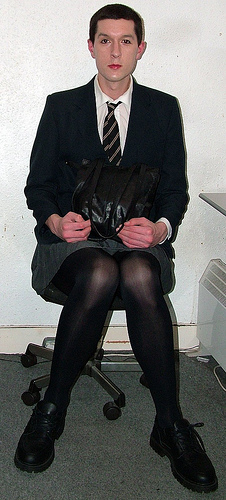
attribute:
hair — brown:
[77, 1, 145, 29]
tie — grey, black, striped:
[102, 100, 122, 166]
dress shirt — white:
[92, 72, 132, 155]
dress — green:
[32, 238, 173, 289]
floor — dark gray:
[0, 352, 225, 498]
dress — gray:
[30, 243, 174, 298]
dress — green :
[32, 228, 175, 294]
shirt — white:
[91, 72, 134, 164]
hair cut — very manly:
[81, 0, 146, 45]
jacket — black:
[24, 74, 189, 258]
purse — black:
[68, 156, 160, 239]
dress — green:
[30, 235, 176, 295]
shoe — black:
[11, 399, 65, 472]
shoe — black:
[147, 413, 218, 493]